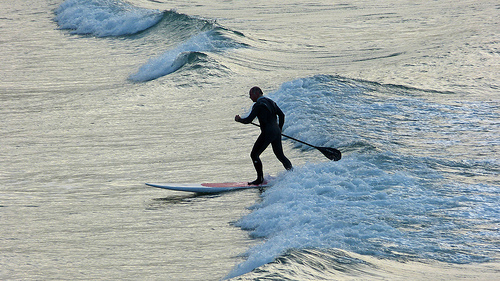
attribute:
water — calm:
[21, 116, 132, 273]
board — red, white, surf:
[152, 169, 270, 200]